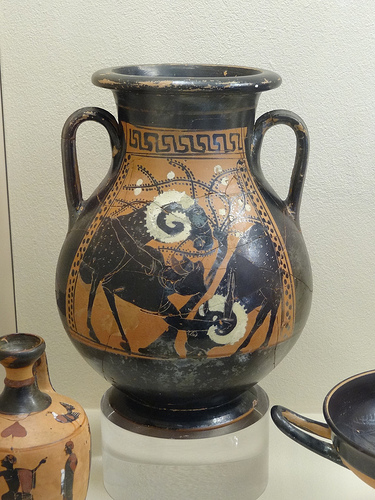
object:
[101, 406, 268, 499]
clear stand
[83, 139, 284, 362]
picture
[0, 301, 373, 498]
shelf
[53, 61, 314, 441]
vase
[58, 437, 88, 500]
drawing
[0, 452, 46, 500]
painted person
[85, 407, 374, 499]
countertop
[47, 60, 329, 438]
pot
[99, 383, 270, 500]
stand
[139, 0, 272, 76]
wall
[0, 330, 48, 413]
spout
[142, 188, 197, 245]
ram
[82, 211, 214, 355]
pic human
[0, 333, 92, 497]
tan vase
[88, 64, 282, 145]
spout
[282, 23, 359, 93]
wall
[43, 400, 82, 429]
bird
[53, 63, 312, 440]
black pottery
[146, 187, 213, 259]
drawing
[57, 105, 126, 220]
handle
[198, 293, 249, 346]
ram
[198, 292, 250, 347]
white horns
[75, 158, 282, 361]
painting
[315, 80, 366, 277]
wall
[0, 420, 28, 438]
spades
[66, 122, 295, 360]
design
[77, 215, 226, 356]
bull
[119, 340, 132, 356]
bull hooves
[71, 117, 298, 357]
drawing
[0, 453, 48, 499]
drawing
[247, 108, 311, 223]
handle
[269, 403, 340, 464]
handle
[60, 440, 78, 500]
painting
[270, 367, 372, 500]
vase